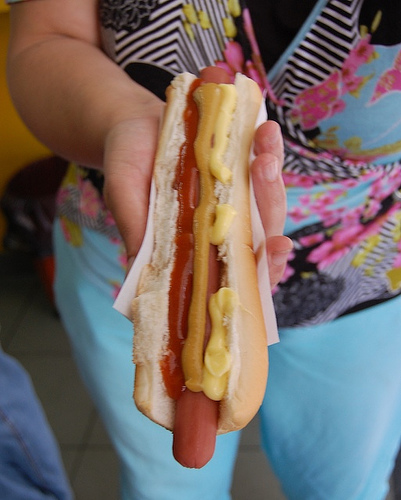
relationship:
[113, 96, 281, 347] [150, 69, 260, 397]
napkin holding hotdog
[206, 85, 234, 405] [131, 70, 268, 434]
cheese on bun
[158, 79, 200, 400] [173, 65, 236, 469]
ketchup on dog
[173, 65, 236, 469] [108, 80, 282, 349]
dog in napkin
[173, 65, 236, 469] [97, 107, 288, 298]
dog in hand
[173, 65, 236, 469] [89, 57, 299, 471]
dog in bun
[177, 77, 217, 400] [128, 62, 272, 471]
mustard on dog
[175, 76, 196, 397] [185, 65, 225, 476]
ketchup on hot dog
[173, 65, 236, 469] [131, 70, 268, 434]
dog between bun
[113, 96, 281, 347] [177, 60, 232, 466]
napkin below hot dog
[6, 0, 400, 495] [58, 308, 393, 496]
person in pants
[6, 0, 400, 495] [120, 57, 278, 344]
person holding hotdog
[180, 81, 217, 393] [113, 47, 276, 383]
mustard on dog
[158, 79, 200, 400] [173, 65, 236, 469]
ketchup slathered on dog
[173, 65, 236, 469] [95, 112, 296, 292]
dog in womans hand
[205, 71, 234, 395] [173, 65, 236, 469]
cheese on dog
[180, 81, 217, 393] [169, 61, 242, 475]
mustard on hot dog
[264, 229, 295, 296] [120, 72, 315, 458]
finger holding hot dog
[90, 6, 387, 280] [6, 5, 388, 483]
shirt of person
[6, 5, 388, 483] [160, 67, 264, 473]
person holding hotdog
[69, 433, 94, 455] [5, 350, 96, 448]
grout between tile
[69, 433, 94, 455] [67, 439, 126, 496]
grout between tile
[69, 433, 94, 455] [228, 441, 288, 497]
grout between tile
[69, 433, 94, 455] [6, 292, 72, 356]
grout between tile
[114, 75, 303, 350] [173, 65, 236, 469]
napkin under dog